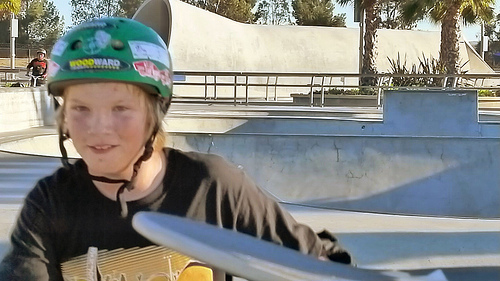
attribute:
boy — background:
[25, 47, 50, 87]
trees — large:
[329, 3, 499, 113]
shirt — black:
[38, 144, 273, 278]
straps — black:
[44, 94, 170, 194]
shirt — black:
[8, 145, 343, 280]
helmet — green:
[44, 17, 171, 96]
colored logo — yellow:
[67, 59, 125, 72]